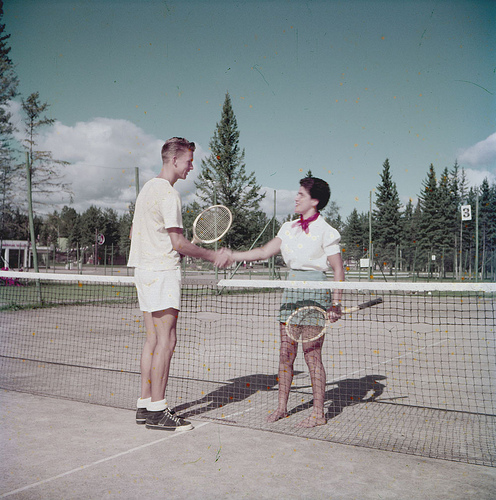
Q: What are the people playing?
A: Badminton.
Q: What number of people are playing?
A: Two.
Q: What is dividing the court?
A: Net.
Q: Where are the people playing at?
A: Court.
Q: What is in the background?
A: Trees.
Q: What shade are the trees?
A: Green.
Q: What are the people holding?
A: Rackets.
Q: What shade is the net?
A: White.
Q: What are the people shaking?
A: Hands.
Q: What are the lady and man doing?
A: Shaking hands.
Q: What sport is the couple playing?
A: Tennis.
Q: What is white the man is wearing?
A: The shirt.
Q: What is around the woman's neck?
A: Red scarf.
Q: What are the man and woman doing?
A: Playing Tennis.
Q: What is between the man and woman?
A: Tennis net.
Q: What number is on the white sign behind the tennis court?
A: 3.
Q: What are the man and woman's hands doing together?
A: Shaking hands.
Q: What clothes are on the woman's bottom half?
A: Shorts.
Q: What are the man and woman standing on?
A: Tennis court.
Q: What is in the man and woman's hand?
A: Tennis racket.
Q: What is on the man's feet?
A: Tennis shoes.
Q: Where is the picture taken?
A: Tennis court.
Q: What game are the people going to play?
A: Tennis.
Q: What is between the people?
A: A net.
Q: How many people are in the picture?
A: Two.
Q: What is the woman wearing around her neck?
A: A scarf.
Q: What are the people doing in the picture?
A: Shaking hands.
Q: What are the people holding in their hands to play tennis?
A: Rackets.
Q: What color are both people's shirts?
A: White.